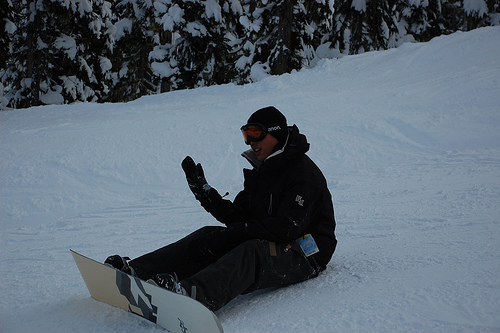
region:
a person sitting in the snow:
[22, 89, 411, 328]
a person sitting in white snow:
[29, 92, 430, 332]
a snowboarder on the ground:
[54, 102, 436, 331]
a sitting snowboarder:
[61, 78, 372, 330]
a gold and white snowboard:
[49, 233, 264, 323]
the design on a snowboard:
[99, 272, 185, 332]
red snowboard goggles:
[226, 122, 280, 144]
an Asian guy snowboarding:
[72, 63, 380, 328]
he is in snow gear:
[134, 80, 407, 313]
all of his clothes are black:
[123, 65, 390, 320]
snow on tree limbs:
[5, 1, 487, 98]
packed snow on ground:
[5, 160, 492, 325]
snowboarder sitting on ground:
[93, 101, 335, 327]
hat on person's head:
[248, 105, 289, 142]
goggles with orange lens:
[237, 118, 267, 146]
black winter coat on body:
[225, 140, 339, 266]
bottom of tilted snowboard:
[67, 250, 225, 332]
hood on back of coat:
[285, 122, 314, 156]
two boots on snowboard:
[105, 254, 195, 294]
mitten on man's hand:
[178, 153, 215, 210]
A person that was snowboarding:
[86, 90, 362, 315]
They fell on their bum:
[147, 138, 241, 223]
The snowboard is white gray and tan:
[71, 235, 182, 330]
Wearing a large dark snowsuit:
[146, 95, 351, 304]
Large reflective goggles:
[234, 115, 277, 147]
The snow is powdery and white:
[31, 127, 143, 153]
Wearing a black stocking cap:
[239, 102, 289, 165]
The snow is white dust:
[48, 117, 122, 194]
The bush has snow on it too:
[53, 17, 149, 104]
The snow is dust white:
[36, 116, 117, 196]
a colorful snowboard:
[57, 240, 223, 332]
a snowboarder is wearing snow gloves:
[170, 152, 217, 196]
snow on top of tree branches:
[0, 0, 452, 45]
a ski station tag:
[295, 229, 327, 262]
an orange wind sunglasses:
[235, 120, 272, 145]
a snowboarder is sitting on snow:
[60, 98, 345, 331]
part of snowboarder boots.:
[151, 267, 205, 294]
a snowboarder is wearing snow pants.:
[187, 241, 314, 293]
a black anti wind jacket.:
[215, 153, 333, 240]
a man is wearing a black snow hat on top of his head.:
[246, 102, 304, 136]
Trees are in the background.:
[0, 0, 499, 107]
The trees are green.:
[0, 0, 499, 110]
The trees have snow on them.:
[0, 0, 499, 110]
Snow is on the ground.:
[0, 23, 499, 331]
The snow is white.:
[0, 26, 499, 331]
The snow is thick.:
[1, 24, 499, 331]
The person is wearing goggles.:
[237, 121, 289, 142]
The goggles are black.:
[239, 120, 290, 145]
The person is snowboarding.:
[67, 104, 338, 331]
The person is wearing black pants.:
[105, 222, 337, 312]